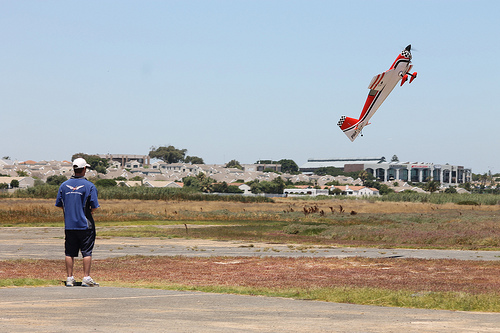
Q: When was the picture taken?
A: Daytime.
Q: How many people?
A: 1.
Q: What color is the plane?
A: Red,white and black.